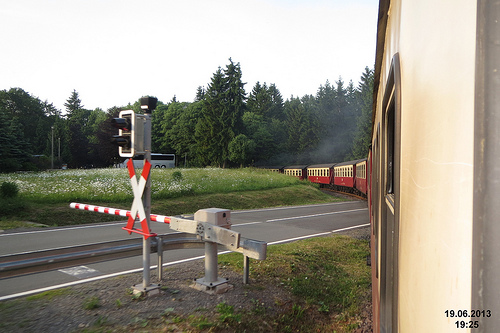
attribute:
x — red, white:
[124, 156, 152, 239]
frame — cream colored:
[307, 164, 331, 179]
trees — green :
[22, 77, 299, 156]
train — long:
[263, 164, 451, 194]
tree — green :
[210, 57, 249, 164]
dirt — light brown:
[1, 256, 287, 331]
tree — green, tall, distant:
[191, 61, 248, 168]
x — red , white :
[117, 155, 158, 240]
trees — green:
[0, 56, 379, 174]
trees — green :
[170, 73, 345, 155]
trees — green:
[194, 67, 288, 180]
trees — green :
[176, 17, 391, 214]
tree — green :
[244, 77, 284, 167]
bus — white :
[107, 144, 185, 176]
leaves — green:
[188, 55, 257, 164]